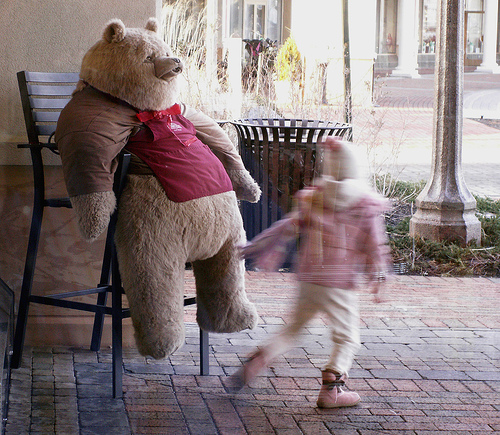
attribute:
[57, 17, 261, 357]
teddy bear — big, brown, giant, huge, tan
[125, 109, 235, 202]
apron — wine colored, red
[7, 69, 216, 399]
chair — black, tall, metal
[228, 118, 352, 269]
garbage can — metal, black, big, large, metal-framed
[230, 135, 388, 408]
girl — little, blurred, small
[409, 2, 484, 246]
lamp post — black, gray, tall, concrete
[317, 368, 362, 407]
boot — black, pink, right boot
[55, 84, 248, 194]
t shirt — brown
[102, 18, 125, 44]
ear — small, furry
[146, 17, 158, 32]
ear — small, furry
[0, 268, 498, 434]
sidewalk — brick, multi colored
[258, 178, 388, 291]
coat — pink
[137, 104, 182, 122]
bowtie — red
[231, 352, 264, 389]
boot — pink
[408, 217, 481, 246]
base — concrete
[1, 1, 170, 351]
wall — beige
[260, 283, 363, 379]
pants — white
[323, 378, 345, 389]
bow — brown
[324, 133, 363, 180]
hat — pink